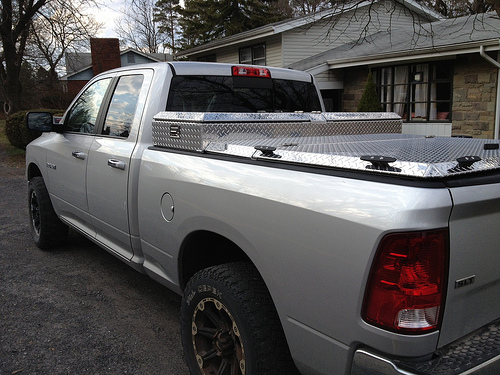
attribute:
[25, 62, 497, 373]
pickup truck — silver, parked, white, gray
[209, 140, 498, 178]
cover — aluminum, metal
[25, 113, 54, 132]
sideview mirror — here, black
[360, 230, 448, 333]
brakelight — red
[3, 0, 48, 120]
tree — leafless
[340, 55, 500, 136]
wall — stone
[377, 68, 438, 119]
curtain — white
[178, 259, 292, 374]
tire — black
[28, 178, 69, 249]
tire — black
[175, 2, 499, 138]
house — here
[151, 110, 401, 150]
tool box — aluminum, metal